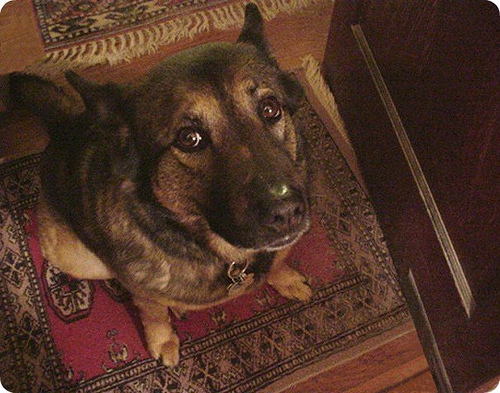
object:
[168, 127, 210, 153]
eyes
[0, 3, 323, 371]
dog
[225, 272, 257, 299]
tags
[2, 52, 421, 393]
rug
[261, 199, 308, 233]
nose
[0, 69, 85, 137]
tail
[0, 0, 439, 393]
floor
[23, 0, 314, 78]
fringe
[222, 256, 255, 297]
collar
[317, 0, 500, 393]
door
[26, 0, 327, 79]
rug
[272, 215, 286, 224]
nostrils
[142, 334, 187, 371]
paws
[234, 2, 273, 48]
ears